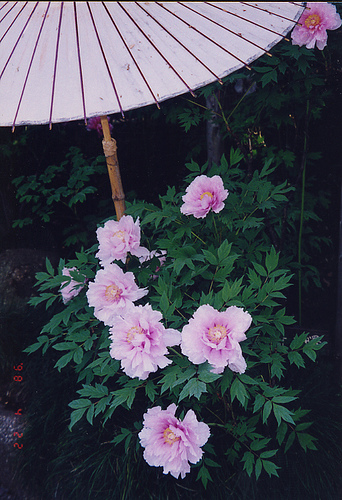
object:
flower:
[129, 244, 168, 280]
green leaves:
[271, 402, 299, 429]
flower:
[289, 0, 342, 53]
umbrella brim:
[0, 0, 310, 139]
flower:
[179, 174, 230, 220]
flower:
[84, 262, 151, 328]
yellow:
[208, 324, 228, 344]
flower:
[179, 301, 252, 375]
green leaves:
[261, 399, 273, 425]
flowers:
[57, 265, 90, 308]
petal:
[210, 201, 225, 215]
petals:
[168, 422, 198, 458]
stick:
[100, 116, 129, 224]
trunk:
[203, 78, 226, 168]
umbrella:
[0, 0, 314, 138]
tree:
[21, 134, 330, 500]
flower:
[137, 400, 212, 481]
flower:
[107, 301, 184, 384]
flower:
[94, 214, 151, 268]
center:
[163, 427, 180, 446]